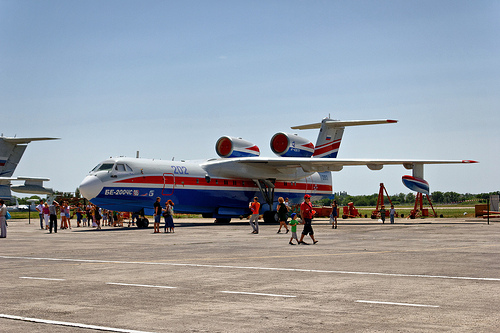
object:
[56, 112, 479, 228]
plane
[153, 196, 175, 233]
group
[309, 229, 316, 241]
leg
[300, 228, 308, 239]
leg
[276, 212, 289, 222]
dress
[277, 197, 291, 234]
people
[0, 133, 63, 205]
airplane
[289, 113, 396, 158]
tail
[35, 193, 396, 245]
some peopel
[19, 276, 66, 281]
marking strip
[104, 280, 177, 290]
marking strip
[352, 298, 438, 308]
marking strip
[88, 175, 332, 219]
colors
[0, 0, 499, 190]
sky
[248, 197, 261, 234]
people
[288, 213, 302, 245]
child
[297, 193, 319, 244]
adult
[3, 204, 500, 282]
fields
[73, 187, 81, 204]
tree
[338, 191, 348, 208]
tree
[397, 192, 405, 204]
tree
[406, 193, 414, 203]
tree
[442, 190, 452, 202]
tree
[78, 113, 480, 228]
aircraft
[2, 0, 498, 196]
blue sky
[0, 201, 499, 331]
land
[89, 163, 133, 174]
window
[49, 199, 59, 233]
people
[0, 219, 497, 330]
ground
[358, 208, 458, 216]
grass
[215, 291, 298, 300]
lines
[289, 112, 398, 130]
top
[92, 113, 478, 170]
top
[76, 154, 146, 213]
front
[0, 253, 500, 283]
line